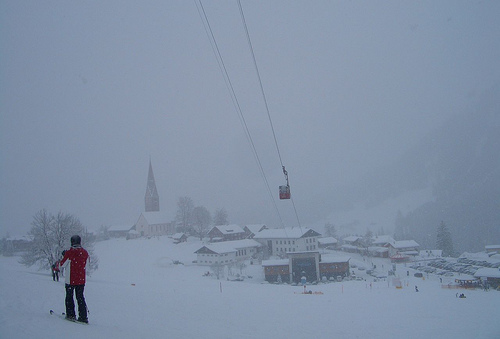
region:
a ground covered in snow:
[255, 281, 340, 332]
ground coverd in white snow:
[334, 297, 421, 332]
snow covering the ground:
[341, 309, 421, 334]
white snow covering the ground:
[314, 291, 432, 334]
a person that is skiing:
[54, 190, 164, 335]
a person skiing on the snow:
[42, 220, 104, 287]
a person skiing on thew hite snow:
[49, 225, 132, 331]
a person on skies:
[22, 221, 119, 337]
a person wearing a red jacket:
[58, 218, 146, 336]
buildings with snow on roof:
[215, 193, 310, 321]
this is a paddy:
[55, 225, 93, 318]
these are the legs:
[61, 282, 96, 319]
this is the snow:
[161, 286, 233, 335]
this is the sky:
[76, 40, 201, 127]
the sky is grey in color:
[345, 26, 425, 113]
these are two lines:
[213, 87, 287, 146]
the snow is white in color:
[245, 296, 265, 318]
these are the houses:
[205, 234, 336, 278]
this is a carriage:
[276, 180, 291, 198]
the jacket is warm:
[63, 250, 85, 283]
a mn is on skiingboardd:
[31, 214, 124, 320]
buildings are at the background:
[206, 210, 391, 336]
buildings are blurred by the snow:
[247, 211, 309, 270]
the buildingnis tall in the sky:
[128, 157, 185, 232]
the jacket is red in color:
[52, 234, 110, 279]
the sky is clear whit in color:
[71, 50, 142, 139]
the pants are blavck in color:
[53, 286, 121, 328]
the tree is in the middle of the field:
[41, 202, 66, 257]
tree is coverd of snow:
[46, 229, 78, 278]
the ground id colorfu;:
[358, 235, 436, 295]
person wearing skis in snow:
[47, 229, 92, 328]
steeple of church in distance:
[141, 151, 159, 211]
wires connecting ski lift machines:
[193, 4, 321, 249]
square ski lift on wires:
[279, 164, 291, 199]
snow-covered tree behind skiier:
[23, 206, 98, 281]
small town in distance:
[198, 213, 425, 286]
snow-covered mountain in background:
[332, 67, 498, 257]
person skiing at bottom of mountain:
[411, 281, 422, 293]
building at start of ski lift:
[260, 245, 348, 285]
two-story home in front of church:
[132, 208, 176, 238]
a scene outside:
[2, 2, 498, 337]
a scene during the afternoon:
[5, 5, 497, 336]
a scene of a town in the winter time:
[5, 8, 496, 337]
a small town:
[116, 146, 498, 311]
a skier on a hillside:
[3, 227, 498, 334]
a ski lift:
[183, 0, 330, 257]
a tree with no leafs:
[18, 200, 105, 275]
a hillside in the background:
[335, 51, 498, 254]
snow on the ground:
[1, 239, 498, 336]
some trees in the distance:
[164, 180, 239, 239]